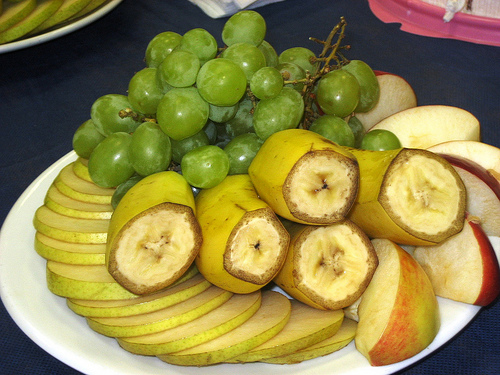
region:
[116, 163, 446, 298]
Bananas on the plate.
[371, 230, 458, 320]
Sliced apples under the banana.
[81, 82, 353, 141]
Grapes on top of bananas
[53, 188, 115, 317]
Green sliced apples.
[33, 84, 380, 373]
Fruits on the plate.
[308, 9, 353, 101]
stem of the green grapes.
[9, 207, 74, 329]
The plate is white.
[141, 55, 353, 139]
The grapes are green.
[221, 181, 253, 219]
The banana peeling has brown spots.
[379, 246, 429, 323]
The peeling on the apple.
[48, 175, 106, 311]
The fruit on the plate is sliced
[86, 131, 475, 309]
The banana fruit are cut into pieces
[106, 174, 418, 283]
The banana are the color yellow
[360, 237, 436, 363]
The slice of an apple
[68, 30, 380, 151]
The grapes are on the stem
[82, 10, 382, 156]
The grapes are the color green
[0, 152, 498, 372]
The plate is the color white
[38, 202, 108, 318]
The fruit is the color yellow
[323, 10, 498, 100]
The table cloth is the color blue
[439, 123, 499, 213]
The apple is the color red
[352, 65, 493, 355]
Apples are on the plate.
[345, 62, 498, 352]
The apples are red.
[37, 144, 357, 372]
The green apples are on the plate.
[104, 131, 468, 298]
The bananas are yellow.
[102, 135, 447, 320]
The bananas are turning brown.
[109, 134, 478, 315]
The bananas are on the plate.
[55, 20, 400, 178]
The grapes are green.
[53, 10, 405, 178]
The grapes are on the plate.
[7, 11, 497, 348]
The table cloth is blue.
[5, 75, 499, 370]
The fruit is on the plate.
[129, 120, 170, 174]
Green grape next to green grape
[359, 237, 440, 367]
Apple slice on white round plate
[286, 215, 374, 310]
Half banana leaning on apple sice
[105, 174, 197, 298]
Half banana by green grape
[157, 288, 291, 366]
Sliced pear on white plate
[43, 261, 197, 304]
Sliced pear under half banana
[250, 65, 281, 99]
Green grape next to green grape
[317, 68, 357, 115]
Green grape next to green grape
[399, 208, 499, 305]
Apple slice next to apple slice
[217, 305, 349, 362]
Pear slice on top of pear slice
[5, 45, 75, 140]
Table is blue color.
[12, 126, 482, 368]
Plate is white color.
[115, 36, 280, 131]
Grapes is green color.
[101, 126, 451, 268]
Banana is yellow color.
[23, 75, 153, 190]
Plate is in table.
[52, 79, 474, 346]
Plate is full of fruits.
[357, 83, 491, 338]
Apple is red and yellow color.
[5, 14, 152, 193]
Two plates are in table.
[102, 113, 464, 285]
Banana are cut into halves.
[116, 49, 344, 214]
Grapes are behind the banana.